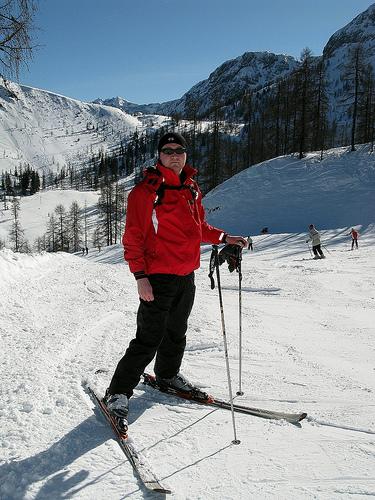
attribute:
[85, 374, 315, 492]
skis — black, red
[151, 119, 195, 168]
hat — black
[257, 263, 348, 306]
snow — white, tracked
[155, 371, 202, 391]
shoe — black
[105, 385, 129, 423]
shoe — black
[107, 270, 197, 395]
pants — black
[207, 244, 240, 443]
pole — white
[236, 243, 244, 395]
pole — white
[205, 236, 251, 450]
poles — black, white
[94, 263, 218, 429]
pants — black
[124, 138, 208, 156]
goggles — black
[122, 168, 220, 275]
jacket — red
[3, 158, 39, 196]
trees — skinny, green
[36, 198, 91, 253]
trees — skinny, green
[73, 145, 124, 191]
trees — skinny, green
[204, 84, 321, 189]
trees — skinny, green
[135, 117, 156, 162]
trees — skinny, green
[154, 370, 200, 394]
boot — silver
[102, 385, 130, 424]
boot — silver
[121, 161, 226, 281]
coat — red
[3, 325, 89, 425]
snow — clumpy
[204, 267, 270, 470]
poles — white, ski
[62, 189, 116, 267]
trees — tall, thin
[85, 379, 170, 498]
ski — red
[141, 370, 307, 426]
ski — red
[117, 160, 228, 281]
jacket — white, black , Red 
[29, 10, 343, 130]
sky — clear, blue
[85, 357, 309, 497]
snow skis — black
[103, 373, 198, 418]
shoes — black, gray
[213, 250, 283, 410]
pole — white, ski